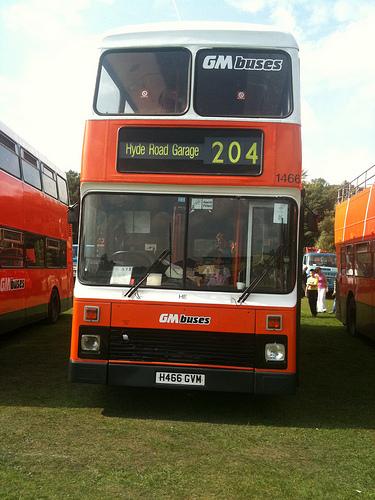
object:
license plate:
[150, 367, 208, 390]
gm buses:
[200, 51, 285, 75]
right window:
[192, 47, 294, 119]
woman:
[314, 265, 329, 313]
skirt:
[316, 285, 328, 317]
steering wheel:
[109, 246, 151, 273]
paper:
[267, 200, 293, 227]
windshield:
[75, 189, 299, 299]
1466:
[274, 169, 303, 190]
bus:
[68, 18, 311, 405]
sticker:
[236, 89, 247, 105]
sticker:
[137, 87, 151, 101]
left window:
[95, 47, 190, 116]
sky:
[0, 1, 374, 188]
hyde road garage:
[116, 140, 207, 164]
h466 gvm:
[155, 371, 203, 388]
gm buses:
[157, 310, 214, 331]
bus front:
[68, 299, 295, 389]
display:
[114, 124, 265, 177]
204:
[207, 140, 261, 169]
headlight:
[260, 340, 286, 363]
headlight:
[78, 334, 101, 357]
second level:
[85, 19, 302, 130]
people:
[303, 271, 318, 318]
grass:
[2, 291, 374, 499]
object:
[119, 333, 133, 343]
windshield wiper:
[123, 242, 170, 304]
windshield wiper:
[235, 243, 290, 307]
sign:
[108, 263, 135, 286]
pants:
[304, 289, 318, 317]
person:
[200, 249, 231, 292]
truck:
[301, 250, 340, 300]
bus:
[329, 159, 374, 352]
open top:
[327, 162, 374, 209]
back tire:
[341, 289, 360, 335]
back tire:
[45, 282, 66, 329]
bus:
[0, 119, 75, 350]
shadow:
[0, 319, 372, 428]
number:
[202, 134, 263, 167]